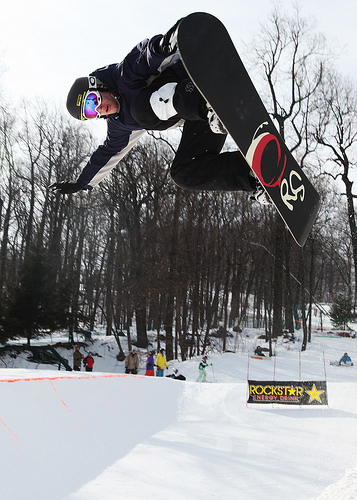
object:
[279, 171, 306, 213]
rs logo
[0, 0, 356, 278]
cloud cover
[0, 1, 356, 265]
sky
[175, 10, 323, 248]
bottom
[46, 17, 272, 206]
man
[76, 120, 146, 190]
arm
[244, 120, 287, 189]
emblem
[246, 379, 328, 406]
banner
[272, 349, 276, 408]
pole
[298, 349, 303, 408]
pole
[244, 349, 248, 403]
pole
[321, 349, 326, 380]
pole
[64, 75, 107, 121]
helmet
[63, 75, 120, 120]
head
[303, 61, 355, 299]
tree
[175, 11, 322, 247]
snowboard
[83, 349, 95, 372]
skier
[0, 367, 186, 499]
slope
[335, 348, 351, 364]
skier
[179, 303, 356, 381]
slope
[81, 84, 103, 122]
goggles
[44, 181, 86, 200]
glove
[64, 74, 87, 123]
hat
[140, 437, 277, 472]
shadow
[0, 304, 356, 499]
snow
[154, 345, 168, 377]
fans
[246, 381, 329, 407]
event